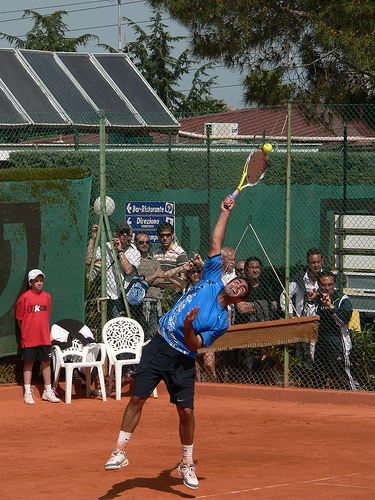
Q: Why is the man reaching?
A: For the ball.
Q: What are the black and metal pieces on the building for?
A: A roof.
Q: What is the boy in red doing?
A: Watching.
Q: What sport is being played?
A: Tennis.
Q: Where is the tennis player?
A: On tennis court.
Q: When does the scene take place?
A: During the daytime.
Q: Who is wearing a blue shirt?
A: Tennis player.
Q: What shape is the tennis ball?
A: Round.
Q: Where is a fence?
A: Behind tennis player.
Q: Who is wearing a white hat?
A: Man in red shirt.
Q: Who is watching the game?
A: Spectators.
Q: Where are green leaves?
A: On trees.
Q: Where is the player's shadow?
A: On the court.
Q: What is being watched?
A: Tennis match.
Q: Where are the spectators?
A: Behind the fence.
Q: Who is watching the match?
A: The men.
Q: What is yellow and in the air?
A: Ball.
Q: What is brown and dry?
A: Dirt.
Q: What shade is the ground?
A: Brown.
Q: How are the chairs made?
A: Out of plastic.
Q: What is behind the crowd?
A: Green wall.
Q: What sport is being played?
A: Tennis.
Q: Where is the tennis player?
A: At the tennis court.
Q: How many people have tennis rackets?
A: 1.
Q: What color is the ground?
A: Red.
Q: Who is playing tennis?
A: A man.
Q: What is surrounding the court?
A: A fence.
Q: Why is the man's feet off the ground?
A: He's jumping.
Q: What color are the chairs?
A: White.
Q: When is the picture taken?
A: Daytime.